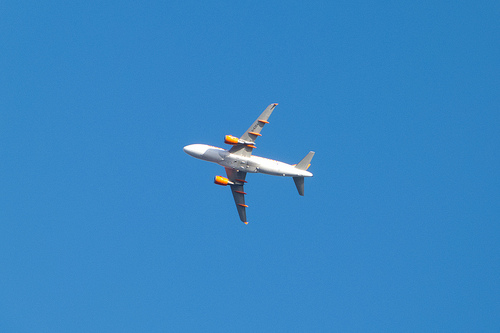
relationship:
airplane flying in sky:
[183, 103, 316, 225] [1, 0, 500, 332]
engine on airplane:
[224, 135, 244, 145] [183, 103, 316, 225]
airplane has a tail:
[183, 103, 316, 225] [283, 162, 314, 177]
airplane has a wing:
[183, 103, 316, 225] [228, 103, 279, 159]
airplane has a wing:
[183, 103, 316, 225] [224, 167, 249, 225]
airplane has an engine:
[183, 103, 316, 225] [213, 175, 234, 186]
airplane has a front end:
[183, 103, 316, 225] [183, 143, 209, 159]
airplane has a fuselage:
[183, 103, 316, 225] [201, 144, 279, 176]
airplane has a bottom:
[183, 103, 316, 225] [183, 147, 313, 178]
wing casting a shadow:
[228, 103, 279, 159] [203, 143, 252, 161]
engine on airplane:
[213, 175, 234, 186] [183, 103, 316, 225]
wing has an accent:
[228, 103, 279, 159] [274, 103, 278, 105]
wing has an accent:
[228, 103, 279, 159] [258, 119, 269, 124]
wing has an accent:
[228, 103, 279, 159] [248, 131, 262, 136]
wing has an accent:
[228, 103, 279, 159] [246, 144, 256, 149]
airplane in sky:
[183, 103, 316, 225] [1, 0, 500, 332]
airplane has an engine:
[183, 103, 316, 225] [224, 135, 244, 145]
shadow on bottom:
[203, 143, 252, 161] [183, 147, 313, 178]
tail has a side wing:
[283, 162, 314, 177] [295, 151, 316, 171]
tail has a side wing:
[283, 162, 314, 177] [292, 176, 304, 196]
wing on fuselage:
[228, 103, 279, 159] [201, 144, 279, 176]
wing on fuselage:
[224, 167, 249, 225] [201, 144, 279, 176]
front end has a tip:
[183, 143, 209, 159] [182, 146, 187, 152]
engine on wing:
[224, 135, 244, 145] [228, 103, 279, 159]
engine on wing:
[213, 175, 234, 186] [224, 167, 249, 225]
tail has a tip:
[283, 162, 314, 177] [308, 172, 313, 177]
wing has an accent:
[224, 167, 249, 225] [236, 178, 248, 184]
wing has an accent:
[224, 167, 249, 225] [233, 190, 246, 196]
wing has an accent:
[224, 167, 249, 225] [237, 203, 247, 208]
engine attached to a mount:
[224, 135, 244, 145] [240, 138, 255, 145]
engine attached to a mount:
[213, 175, 234, 186] [230, 180, 245, 185]